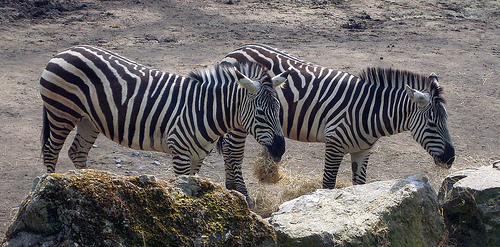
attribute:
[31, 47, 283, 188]
zebra — black, white, standing, eating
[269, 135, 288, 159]
nose — black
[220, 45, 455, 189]
zebra — black, white, standing, grazing, eating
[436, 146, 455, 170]
nose — black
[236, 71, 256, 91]
ear — white, black, large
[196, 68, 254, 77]
mane — black, white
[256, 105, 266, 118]
eye — open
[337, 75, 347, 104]
stripe — black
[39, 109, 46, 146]
hair — black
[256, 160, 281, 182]
hay — dried